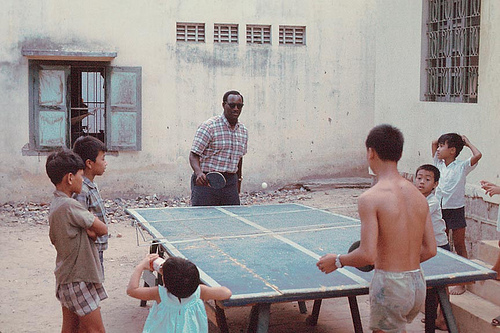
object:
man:
[186, 90, 253, 207]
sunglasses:
[224, 101, 245, 108]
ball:
[261, 182, 268, 190]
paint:
[203, 240, 283, 297]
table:
[119, 196, 498, 333]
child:
[125, 253, 234, 333]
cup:
[153, 256, 165, 277]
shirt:
[43, 189, 107, 287]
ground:
[0, 184, 450, 332]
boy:
[45, 148, 110, 330]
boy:
[68, 134, 110, 278]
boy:
[429, 131, 480, 295]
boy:
[410, 163, 452, 252]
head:
[73, 135, 108, 176]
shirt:
[188, 113, 250, 175]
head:
[45, 149, 85, 196]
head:
[160, 257, 202, 298]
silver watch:
[335, 253, 344, 269]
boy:
[315, 123, 440, 331]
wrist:
[333, 253, 346, 268]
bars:
[436, 32, 440, 67]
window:
[422, 2, 483, 104]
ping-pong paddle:
[205, 171, 227, 190]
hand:
[193, 172, 212, 188]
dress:
[140, 283, 209, 333]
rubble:
[99, 194, 169, 215]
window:
[30, 59, 143, 151]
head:
[414, 164, 441, 195]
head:
[437, 133, 465, 161]